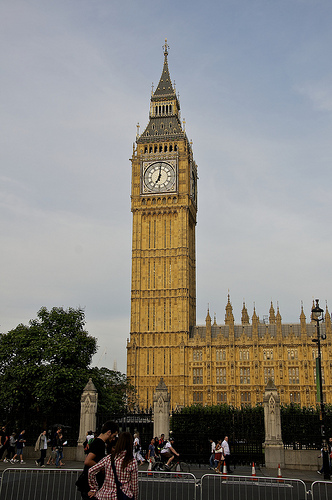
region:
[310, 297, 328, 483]
a tall black street lamp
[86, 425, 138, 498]
a lady wearing a red and white plaid shirt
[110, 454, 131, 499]
the lady has a black bag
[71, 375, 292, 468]
three pillars in front of the building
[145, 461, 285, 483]
orange and white cones be the sidewalk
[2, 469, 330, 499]
a silver fence in front of the couple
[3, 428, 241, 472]
a large group of people walking on the sidewalk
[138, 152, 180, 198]
a large clock on the tower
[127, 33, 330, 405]
the tower is connected to a building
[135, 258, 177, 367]
the building looks like a gold color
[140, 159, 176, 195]
a clock on the tower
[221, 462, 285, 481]
three orange safety cones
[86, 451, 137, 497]
a red plaid shirt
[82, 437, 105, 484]
man is wearing a black tee shirt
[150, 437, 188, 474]
a man riding a bike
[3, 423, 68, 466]
people walking on the sidewalk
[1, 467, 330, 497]
movable metal fencing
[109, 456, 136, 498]
a black shoulder bag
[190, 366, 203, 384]
large window on the building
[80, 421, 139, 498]
man and a woman standing together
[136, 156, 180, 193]
a clock on the the wall of a castle building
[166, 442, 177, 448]
the hand of a person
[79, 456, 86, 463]
the elbow of a person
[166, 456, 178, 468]
the leg of a person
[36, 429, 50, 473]
a man walking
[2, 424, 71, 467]
a group of people walking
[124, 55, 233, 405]
a castle building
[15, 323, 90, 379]
green leaves of a tree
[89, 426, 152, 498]
two people standing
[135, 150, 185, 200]
large clock face on side of tower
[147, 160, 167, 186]
black metal clock hands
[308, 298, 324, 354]
black metal street light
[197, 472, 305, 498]
silver metal guard railing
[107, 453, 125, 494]
black strap on purse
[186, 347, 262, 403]
row of windows on side of building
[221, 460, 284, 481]
row of orange traffic cones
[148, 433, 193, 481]
man riding bike on sidewalk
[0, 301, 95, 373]
tree covered in green leaves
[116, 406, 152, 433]
black metal guard fencing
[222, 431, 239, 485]
This is a person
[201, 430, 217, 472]
This is a person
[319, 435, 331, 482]
This is a person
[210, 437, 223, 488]
This is a person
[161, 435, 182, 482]
This is a person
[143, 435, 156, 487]
This is a person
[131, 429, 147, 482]
This is a person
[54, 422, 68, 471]
This is a person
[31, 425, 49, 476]
This is a person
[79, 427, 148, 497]
girl wearing red plaid shirt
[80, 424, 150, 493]
girl wearing red plaid shirt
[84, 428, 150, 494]
girl wearing red plaid shirt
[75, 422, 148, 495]
girl wearing red plaid shirt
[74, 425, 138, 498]
girl wearing red plaid shirt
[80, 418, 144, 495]
girl wearing red plaid shirt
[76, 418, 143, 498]
girl wearing red plaid shirt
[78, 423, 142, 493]
girl wearing red plaid shirt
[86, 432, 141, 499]
woman with white and red plaid shirt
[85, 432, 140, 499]
woman carrying black purse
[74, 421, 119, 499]
man wearing black shirt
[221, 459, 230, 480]
orange and silver traffic cone